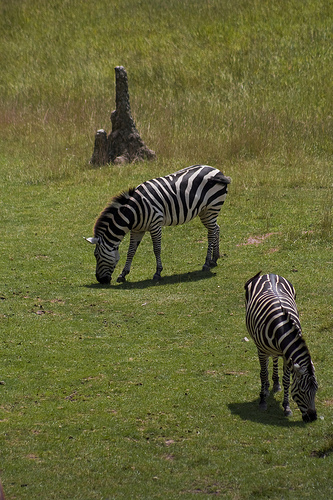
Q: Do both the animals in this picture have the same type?
A: Yes, all the animals are zebras.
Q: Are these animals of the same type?
A: Yes, all the animals are zebras.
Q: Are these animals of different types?
A: No, all the animals are zebras.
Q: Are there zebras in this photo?
A: Yes, there is a zebra.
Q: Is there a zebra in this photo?
A: Yes, there is a zebra.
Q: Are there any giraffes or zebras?
A: Yes, there is a zebra.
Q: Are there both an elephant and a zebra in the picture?
A: No, there is a zebra but no elephants.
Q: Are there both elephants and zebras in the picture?
A: No, there is a zebra but no elephants.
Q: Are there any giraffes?
A: No, there are no giraffes.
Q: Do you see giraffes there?
A: No, there are no giraffes.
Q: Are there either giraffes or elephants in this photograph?
A: No, there are no giraffes or elephants.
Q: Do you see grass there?
A: Yes, there is grass.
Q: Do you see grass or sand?
A: Yes, there is grass.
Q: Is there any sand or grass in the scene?
A: Yes, there is grass.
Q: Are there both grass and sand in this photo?
A: No, there is grass but no sand.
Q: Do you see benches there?
A: No, there are no benches.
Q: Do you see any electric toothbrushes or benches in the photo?
A: No, there are no benches or electric toothbrushes.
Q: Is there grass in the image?
A: Yes, there is grass.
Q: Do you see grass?
A: Yes, there is grass.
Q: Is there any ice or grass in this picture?
A: Yes, there is grass.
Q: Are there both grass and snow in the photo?
A: No, there is grass but no snow.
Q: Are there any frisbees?
A: No, there are no frisbees.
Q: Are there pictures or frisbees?
A: No, there are no frisbees or pictures.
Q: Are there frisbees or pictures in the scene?
A: No, there are no frisbees or pictures.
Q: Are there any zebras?
A: Yes, there is a zebra.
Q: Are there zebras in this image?
A: Yes, there is a zebra.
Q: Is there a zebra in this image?
A: Yes, there is a zebra.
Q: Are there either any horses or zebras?
A: Yes, there is a zebra.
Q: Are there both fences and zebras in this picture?
A: No, there is a zebra but no fences.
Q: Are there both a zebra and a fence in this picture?
A: No, there is a zebra but no fences.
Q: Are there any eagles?
A: No, there are no eagles.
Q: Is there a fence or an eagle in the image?
A: No, there are no eagles or fences.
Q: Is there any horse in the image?
A: No, there are no horses.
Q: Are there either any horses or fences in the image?
A: No, there are no horses or fences.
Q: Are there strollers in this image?
A: No, there are no strollers.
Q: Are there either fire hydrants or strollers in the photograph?
A: No, there are no strollers or fire hydrants.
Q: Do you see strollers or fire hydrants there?
A: No, there are no strollers or fire hydrants.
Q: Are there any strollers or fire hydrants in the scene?
A: No, there are no strollers or fire hydrants.